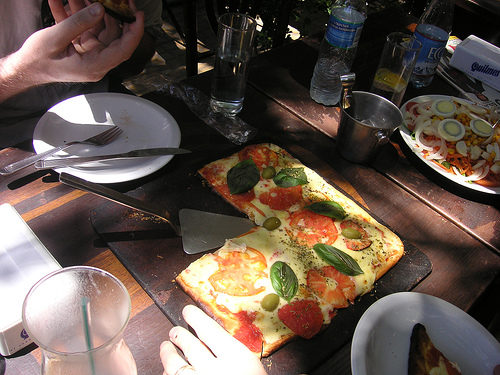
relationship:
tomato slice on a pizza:
[273, 296, 325, 336] [168, 142, 408, 362]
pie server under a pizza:
[86, 204, 255, 256] [168, 142, 408, 362]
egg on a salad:
[437, 118, 465, 141] [404, 96, 498, 188]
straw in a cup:
[77, 296, 104, 370] [24, 265, 142, 372]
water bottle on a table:
[308, 9, 360, 107] [232, 5, 490, 248]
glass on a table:
[209, 12, 257, 118] [6, 64, 496, 373]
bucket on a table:
[335, 91, 402, 161] [230, 13, 499, 263]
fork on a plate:
[0, 126, 123, 177] [33, 92, 183, 184]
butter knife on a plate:
[34, 148, 192, 170] [35, 93, 180, 189]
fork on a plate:
[30, 91, 180, 192] [4, 125, 114, 175]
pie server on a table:
[59, 172, 257, 255] [6, 64, 496, 373]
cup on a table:
[22, 266, 132, 375] [6, 64, 496, 373]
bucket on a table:
[335, 91, 403, 163] [222, 20, 487, 247]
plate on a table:
[350, 287, 499, 368] [0, 0, 500, 372]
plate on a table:
[393, 87, 498, 199] [232, 5, 490, 248]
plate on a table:
[33, 92, 183, 184] [6, 64, 496, 373]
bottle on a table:
[397, 11, 455, 92] [252, 16, 499, 277]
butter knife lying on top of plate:
[34, 148, 192, 170] [30, 89, 183, 187]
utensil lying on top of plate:
[1, 126, 124, 176] [30, 89, 183, 187]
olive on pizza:
[262, 289, 284, 310] [168, 142, 408, 362]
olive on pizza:
[260, 208, 284, 228] [168, 142, 408, 362]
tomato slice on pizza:
[209, 242, 272, 302] [168, 142, 408, 362]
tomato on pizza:
[284, 210, 338, 248] [168, 142, 408, 362]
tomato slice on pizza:
[303, 261, 360, 301] [168, 142, 408, 362]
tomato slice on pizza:
[240, 140, 286, 170] [168, 142, 408, 362]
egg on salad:
[434, 115, 471, 142] [395, 93, 498, 196]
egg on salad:
[426, 95, 464, 116] [395, 93, 498, 196]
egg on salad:
[470, 111, 494, 136] [395, 93, 498, 196]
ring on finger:
[163, 358, 190, 373] [154, 333, 189, 373]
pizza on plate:
[168, 142, 408, 362] [89, 140, 430, 369]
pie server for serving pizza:
[59, 172, 257, 255] [168, 142, 408, 362]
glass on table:
[209, 12, 257, 118] [0, 0, 500, 372]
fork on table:
[0, 126, 123, 177] [32, 88, 183, 185]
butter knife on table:
[34, 148, 192, 170] [32, 88, 183, 185]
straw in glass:
[81, 296, 99, 374] [20, 262, 132, 370]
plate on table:
[30, 89, 183, 187] [0, 0, 500, 372]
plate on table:
[398, 94, 500, 194] [0, 0, 500, 372]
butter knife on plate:
[34, 148, 192, 170] [30, 89, 183, 187]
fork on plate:
[0, 126, 123, 177] [30, 89, 183, 187]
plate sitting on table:
[89, 140, 432, 375] [0, 0, 500, 372]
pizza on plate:
[168, 142, 408, 362] [89, 140, 432, 375]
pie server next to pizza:
[59, 172, 257, 255] [168, 142, 408, 362]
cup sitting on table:
[22, 266, 132, 375] [0, 0, 500, 372]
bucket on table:
[335, 91, 403, 163] [0, 0, 500, 372]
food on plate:
[399, 96, 497, 187] [398, 94, 500, 194]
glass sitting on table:
[209, 12, 257, 118] [0, 0, 500, 372]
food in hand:
[48, 0, 142, 61] [1, 2, 149, 102]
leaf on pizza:
[271, 256, 303, 305] [168, 142, 408, 362]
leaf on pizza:
[311, 238, 366, 275] [168, 142, 408, 362]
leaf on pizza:
[300, 196, 352, 223] [168, 142, 408, 362]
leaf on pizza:
[226, 150, 261, 196] [168, 142, 408, 362]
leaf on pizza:
[270, 164, 310, 187] [168, 142, 408, 362]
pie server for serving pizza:
[59, 172, 257, 255] [180, 139, 408, 347]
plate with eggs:
[398, 94, 500, 194] [430, 91, 484, 143]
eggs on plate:
[430, 91, 484, 143] [398, 94, 500, 194]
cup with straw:
[22, 266, 132, 375] [59, 269, 103, 357]